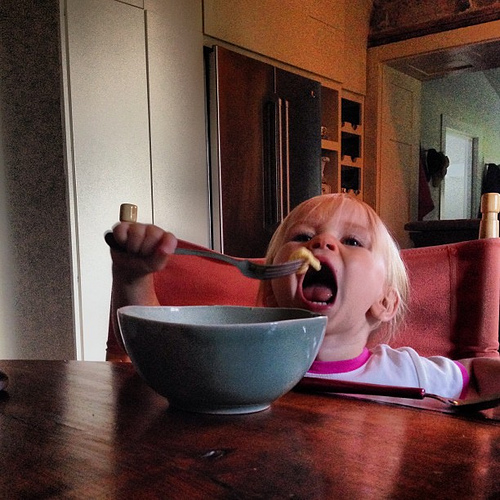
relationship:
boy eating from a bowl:
[104, 193, 500, 401] [115, 304, 327, 415]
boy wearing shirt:
[104, 193, 500, 401] [313, 345, 465, 409]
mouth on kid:
[296, 252, 338, 315] [99, 186, 498, 406]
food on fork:
[288, 246, 322, 275] [175, 246, 305, 293]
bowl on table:
[116, 303, 329, 416] [1, 355, 499, 498]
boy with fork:
[104, 193, 500, 401] [172, 238, 307, 278]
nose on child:
[309, 229, 338, 254] [213, 181, 494, 408]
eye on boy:
[341, 236, 363, 246] [104, 193, 500, 401]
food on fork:
[293, 247, 319, 278] [97, 215, 421, 344]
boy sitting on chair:
[104, 193, 500, 401] [118, 214, 496, 424]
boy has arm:
[104, 193, 500, 401] [414, 347, 498, 404]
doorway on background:
[439, 114, 484, 220] [217, 127, 498, 167]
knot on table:
[201, 438, 222, 459] [6, 354, 498, 484]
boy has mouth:
[269, 184, 494, 401] [295, 256, 342, 310]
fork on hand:
[105, 207, 342, 288] [99, 214, 180, 294]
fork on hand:
[105, 228, 306, 280] [101, 213, 184, 276]